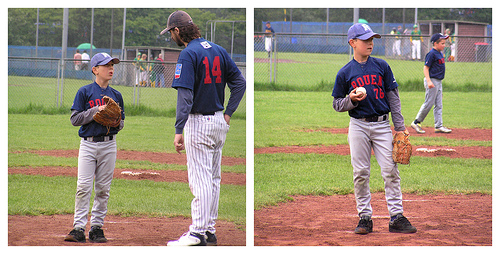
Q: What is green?
A: Grass.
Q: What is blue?
A: Shirts.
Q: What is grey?
A: Pants.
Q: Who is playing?
A: Kids.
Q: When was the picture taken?
A: Daytime.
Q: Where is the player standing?
A: On a field.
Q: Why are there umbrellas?
A: Rain.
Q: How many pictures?
A: Two.